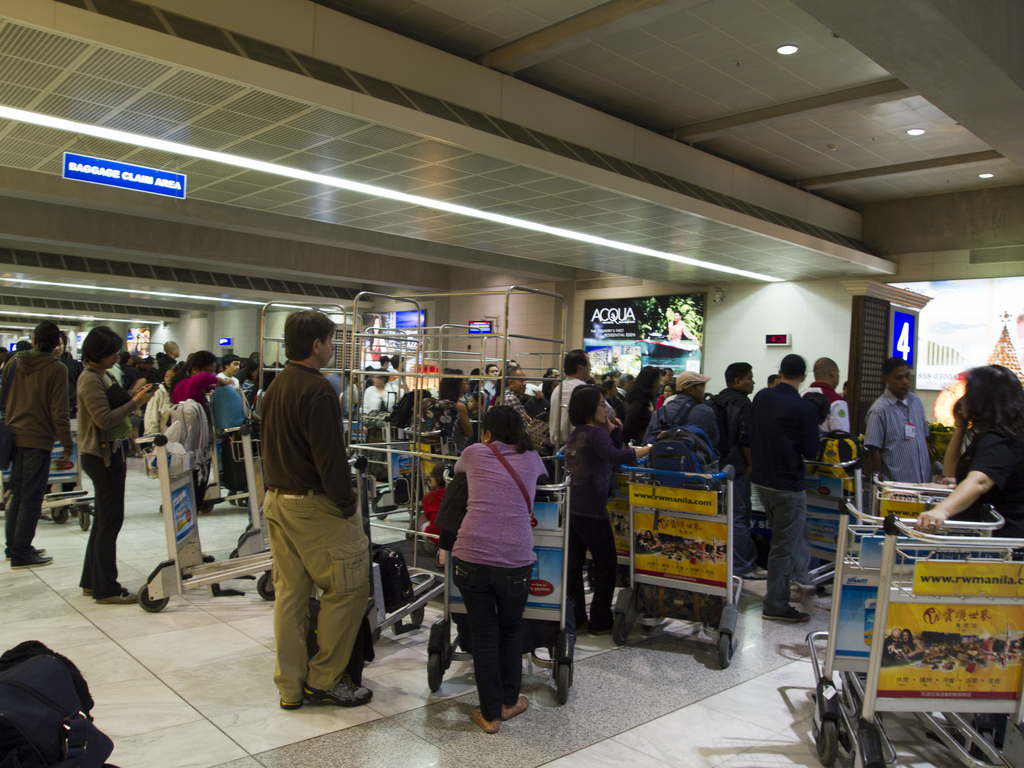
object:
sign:
[879, 300, 930, 383]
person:
[906, 341, 1023, 557]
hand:
[906, 500, 955, 541]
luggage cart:
[778, 453, 1023, 695]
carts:
[842, 509, 1022, 768]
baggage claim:
[0, 152, 979, 286]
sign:
[206, 323, 250, 352]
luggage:
[350, 532, 427, 637]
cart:
[341, 471, 460, 670]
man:
[635, 350, 731, 477]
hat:
[668, 367, 714, 395]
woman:
[405, 366, 613, 745]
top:
[440, 386, 583, 569]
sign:
[44, 137, 232, 206]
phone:
[135, 366, 170, 409]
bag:
[0, 619, 160, 768]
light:
[0, 102, 789, 291]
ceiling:
[0, 0, 1024, 351]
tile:
[534, 629, 618, 715]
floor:
[0, 352, 1024, 767]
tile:
[114, 564, 199, 635]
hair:
[463, 398, 554, 468]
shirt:
[444, 437, 565, 574]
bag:
[406, 458, 492, 550]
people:
[41, 302, 166, 615]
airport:
[0, 0, 1024, 726]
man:
[226, 302, 403, 720]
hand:
[336, 492, 374, 542]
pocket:
[329, 510, 376, 551]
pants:
[258, 482, 379, 716]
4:
[882, 317, 926, 366]